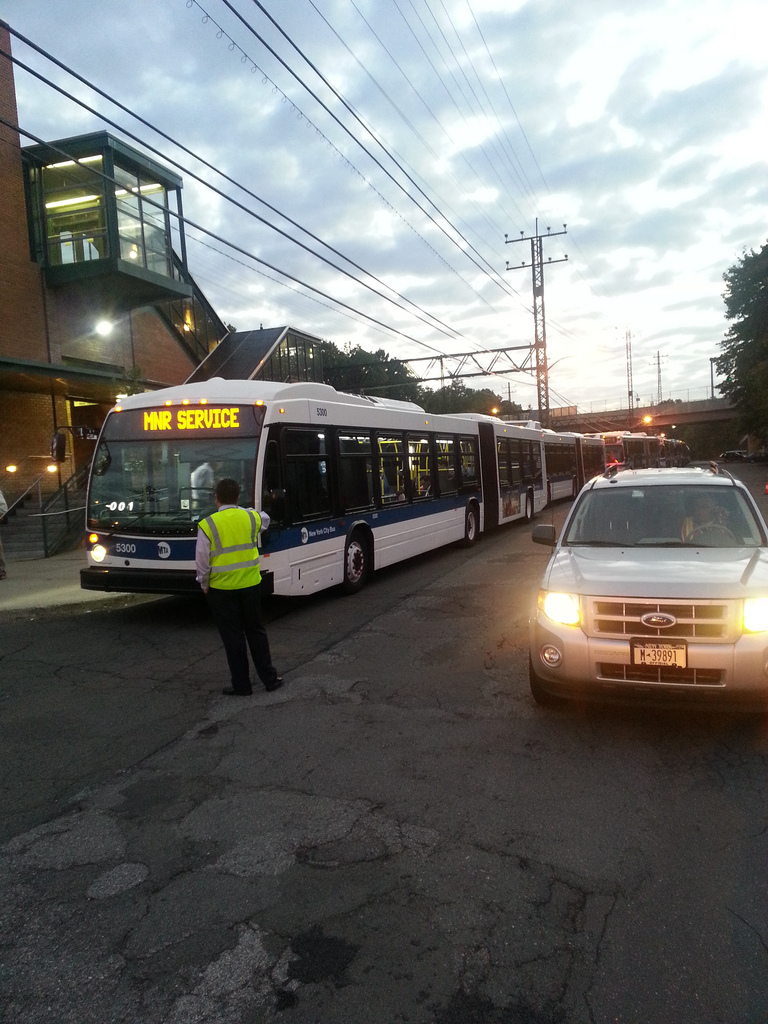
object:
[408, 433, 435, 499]
glass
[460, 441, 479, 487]
glass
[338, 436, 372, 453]
glass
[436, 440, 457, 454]
glass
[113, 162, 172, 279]
window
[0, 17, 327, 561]
building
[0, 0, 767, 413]
air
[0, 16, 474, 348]
wire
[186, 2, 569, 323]
wire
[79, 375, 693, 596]
bus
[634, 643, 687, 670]
license plate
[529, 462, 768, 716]
gray car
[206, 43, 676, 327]
cloudy sky